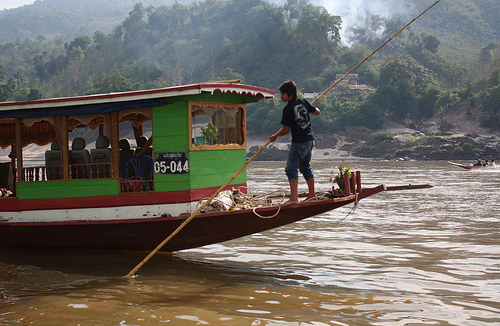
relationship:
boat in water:
[3, 45, 371, 255] [401, 177, 458, 257]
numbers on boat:
[146, 150, 193, 177] [10, 81, 380, 239]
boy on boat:
[268, 78, 319, 208] [1, 75, 391, 260]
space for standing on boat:
[217, 194, 319, 209] [1, 75, 391, 260]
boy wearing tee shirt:
[268, 78, 319, 208] [274, 97, 318, 139]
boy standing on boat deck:
[245, 57, 363, 200] [203, 165, 455, 227]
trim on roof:
[203, 84, 265, 106] [18, 90, 222, 127]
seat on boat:
[88, 146, 115, 173] [1, 75, 391, 260]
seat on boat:
[70, 148, 92, 175] [1, 75, 391, 260]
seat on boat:
[43, 148, 64, 179] [1, 75, 391, 260]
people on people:
[49, 136, 158, 176] [467, 154, 498, 169]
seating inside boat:
[32, 159, 142, 183] [5, 89, 345, 251]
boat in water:
[0, 79, 385, 252] [0, 160, 499, 324]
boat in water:
[444, 152, 499, 169] [0, 160, 499, 324]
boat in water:
[444, 154, 499, 171] [372, 219, 432, 316]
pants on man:
[284, 138, 315, 177] [270, 77, 320, 203]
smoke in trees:
[331, 3, 361, 29] [119, 24, 277, 59]